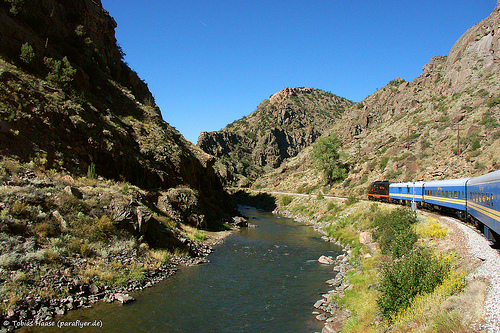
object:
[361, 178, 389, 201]
locomotive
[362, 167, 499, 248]
cars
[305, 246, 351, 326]
rocks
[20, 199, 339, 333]
stream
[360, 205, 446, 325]
shrub brush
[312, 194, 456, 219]
tracks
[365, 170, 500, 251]
train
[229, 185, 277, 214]
shadow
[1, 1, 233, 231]
hill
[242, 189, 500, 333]
shore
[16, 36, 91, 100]
bushes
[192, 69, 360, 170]
hill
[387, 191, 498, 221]
stripe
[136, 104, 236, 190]
rocks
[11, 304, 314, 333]
water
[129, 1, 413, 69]
sky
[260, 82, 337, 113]
top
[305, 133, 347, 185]
tree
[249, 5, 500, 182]
hill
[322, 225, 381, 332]
grass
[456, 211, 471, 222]
wheels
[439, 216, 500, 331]
dirt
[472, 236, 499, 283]
gravel